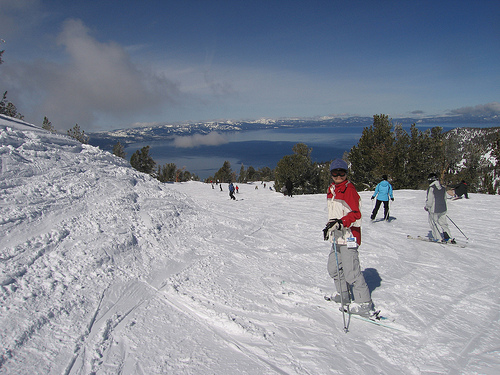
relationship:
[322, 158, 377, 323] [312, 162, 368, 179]
woman with goggles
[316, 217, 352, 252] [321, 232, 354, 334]
hand on pole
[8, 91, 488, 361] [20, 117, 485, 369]
hill with snow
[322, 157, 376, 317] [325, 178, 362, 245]
person wearing a jacket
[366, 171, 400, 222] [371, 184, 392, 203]
person with a jacket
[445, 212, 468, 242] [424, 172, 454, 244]
snow pole behind person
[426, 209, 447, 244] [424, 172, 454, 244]
snow pole behind person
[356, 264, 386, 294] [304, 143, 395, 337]
shadow behind man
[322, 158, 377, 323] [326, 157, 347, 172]
woman wearing hat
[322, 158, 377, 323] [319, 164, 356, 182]
woman wearing goggles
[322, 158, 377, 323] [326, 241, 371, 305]
woman wearing pants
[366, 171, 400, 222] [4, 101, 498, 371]
person on snow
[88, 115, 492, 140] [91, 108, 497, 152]
mountains on background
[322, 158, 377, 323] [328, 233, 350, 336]
woman holding ski poles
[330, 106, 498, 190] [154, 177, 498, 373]
trees behind field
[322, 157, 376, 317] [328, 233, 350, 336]
person holding ski poles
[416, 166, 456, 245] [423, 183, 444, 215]
man wearing jacket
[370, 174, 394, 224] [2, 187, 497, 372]
woman standing in snow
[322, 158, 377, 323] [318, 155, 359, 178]
woman wearing hat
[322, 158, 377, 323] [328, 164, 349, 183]
woman wearing goggles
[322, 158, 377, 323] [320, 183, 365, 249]
woman wearing jacket